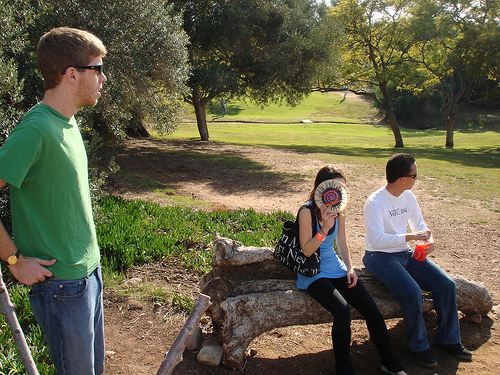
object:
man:
[0, 27, 109, 375]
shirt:
[0, 101, 104, 281]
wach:
[0, 247, 21, 268]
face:
[7, 255, 18, 265]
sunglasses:
[61, 64, 105, 77]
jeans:
[27, 263, 106, 375]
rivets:
[58, 284, 65, 289]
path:
[94, 139, 500, 375]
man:
[361, 152, 472, 369]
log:
[198, 234, 495, 373]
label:
[413, 245, 427, 261]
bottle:
[413, 238, 433, 262]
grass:
[89, 193, 299, 281]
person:
[293, 165, 409, 375]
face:
[406, 162, 419, 190]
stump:
[153, 292, 214, 375]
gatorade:
[413, 239, 431, 262]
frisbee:
[314, 180, 351, 215]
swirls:
[326, 192, 337, 204]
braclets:
[315, 231, 326, 242]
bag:
[271, 204, 322, 277]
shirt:
[294, 200, 349, 290]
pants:
[307, 276, 405, 375]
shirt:
[362, 186, 434, 255]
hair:
[34, 26, 108, 92]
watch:
[0, 249, 22, 266]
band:
[4, 249, 21, 266]